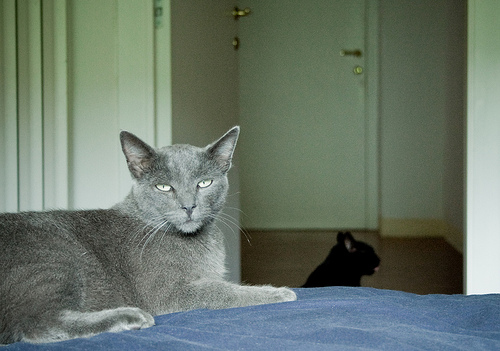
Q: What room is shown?
A: It is a bedroom.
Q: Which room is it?
A: It is a bedroom.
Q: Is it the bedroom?
A: Yes, it is the bedroom.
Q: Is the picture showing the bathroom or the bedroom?
A: It is showing the bedroom.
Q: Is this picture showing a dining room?
A: No, the picture is showing a bedroom.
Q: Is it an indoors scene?
A: Yes, it is indoors.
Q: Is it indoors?
A: Yes, it is indoors.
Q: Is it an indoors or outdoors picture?
A: It is indoors.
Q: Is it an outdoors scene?
A: No, it is indoors.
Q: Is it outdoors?
A: No, it is indoors.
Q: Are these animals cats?
A: Yes, all the animals are cats.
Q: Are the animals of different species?
A: No, all the animals are cats.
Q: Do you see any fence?
A: No, there are no fences.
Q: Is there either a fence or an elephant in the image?
A: No, there are no fences or elephants.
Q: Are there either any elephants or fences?
A: No, there are no fences or elephants.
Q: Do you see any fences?
A: No, there are no fences.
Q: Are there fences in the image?
A: No, there are no fences.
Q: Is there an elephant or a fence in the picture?
A: No, there are no fences or elephants.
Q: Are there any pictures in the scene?
A: No, there are no pictures.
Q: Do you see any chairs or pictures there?
A: No, there are no pictures or chairs.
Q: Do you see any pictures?
A: No, there are no pictures.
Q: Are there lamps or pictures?
A: No, there are no pictures or lamps.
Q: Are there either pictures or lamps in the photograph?
A: No, there are no pictures or lamps.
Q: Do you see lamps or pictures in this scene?
A: No, there are no pictures or lamps.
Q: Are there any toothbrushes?
A: No, there are no toothbrushes.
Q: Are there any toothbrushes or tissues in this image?
A: No, there are no toothbrushes or tissues.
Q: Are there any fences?
A: No, there are no fences.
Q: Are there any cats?
A: Yes, there is a cat.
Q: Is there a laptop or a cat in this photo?
A: Yes, there is a cat.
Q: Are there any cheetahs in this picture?
A: No, there are no cheetahs.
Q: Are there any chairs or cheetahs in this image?
A: No, there are no cheetahs or chairs.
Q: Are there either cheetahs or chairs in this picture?
A: No, there are no cheetahs or chairs.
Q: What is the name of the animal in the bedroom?
A: The animal is a cat.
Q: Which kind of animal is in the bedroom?
A: The animal is a cat.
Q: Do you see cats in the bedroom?
A: Yes, there is a cat in the bedroom.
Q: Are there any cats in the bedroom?
A: Yes, there is a cat in the bedroom.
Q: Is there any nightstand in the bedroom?
A: No, there is a cat in the bedroom.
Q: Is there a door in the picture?
A: Yes, there is a door.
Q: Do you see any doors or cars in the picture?
A: Yes, there is a door.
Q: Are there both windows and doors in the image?
A: No, there is a door but no windows.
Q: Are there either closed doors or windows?
A: Yes, there is a closed door.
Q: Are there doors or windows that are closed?
A: Yes, the door is closed.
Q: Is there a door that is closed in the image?
A: Yes, there is a closed door.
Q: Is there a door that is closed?
A: Yes, there is a door that is closed.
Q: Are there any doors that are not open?
A: Yes, there is an closed door.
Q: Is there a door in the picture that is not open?
A: Yes, there is an closed door.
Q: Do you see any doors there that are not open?
A: Yes, there is an closed door.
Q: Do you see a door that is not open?
A: Yes, there is an closed door.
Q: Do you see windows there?
A: No, there are no windows.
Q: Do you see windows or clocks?
A: No, there are no windows or clocks.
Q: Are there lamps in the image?
A: No, there are no lamps.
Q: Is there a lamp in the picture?
A: No, there are no lamps.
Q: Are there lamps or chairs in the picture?
A: No, there are no lamps or chairs.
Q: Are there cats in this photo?
A: Yes, there is a cat.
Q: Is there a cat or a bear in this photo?
A: Yes, there is a cat.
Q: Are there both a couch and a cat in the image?
A: No, there is a cat but no couches.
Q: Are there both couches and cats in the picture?
A: No, there is a cat but no couches.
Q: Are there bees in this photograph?
A: No, there are no bees.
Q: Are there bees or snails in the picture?
A: No, there are no bees or snails.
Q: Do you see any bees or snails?
A: No, there are no bees or snails.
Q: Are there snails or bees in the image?
A: No, there are no bees or snails.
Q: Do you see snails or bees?
A: No, there are no bees or snails.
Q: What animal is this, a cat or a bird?
A: This is a cat.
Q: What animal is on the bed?
A: The animal is a cat.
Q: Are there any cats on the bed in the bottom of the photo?
A: Yes, there is a cat on the bed.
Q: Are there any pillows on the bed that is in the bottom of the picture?
A: No, there is a cat on the bed.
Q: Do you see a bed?
A: Yes, there is a bed.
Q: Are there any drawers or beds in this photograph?
A: Yes, there is a bed.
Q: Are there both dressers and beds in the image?
A: No, there is a bed but no dressers.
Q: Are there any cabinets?
A: No, there are no cabinets.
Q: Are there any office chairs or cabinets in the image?
A: No, there are no cabinets or office chairs.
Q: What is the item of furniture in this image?
A: The piece of furniture is a bed.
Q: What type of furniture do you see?
A: The furniture is a bed.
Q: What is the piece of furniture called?
A: The piece of furniture is a bed.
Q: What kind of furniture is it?
A: The piece of furniture is a bed.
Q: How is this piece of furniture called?
A: This is a bed.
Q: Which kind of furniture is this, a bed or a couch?
A: This is a bed.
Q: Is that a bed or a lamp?
A: That is a bed.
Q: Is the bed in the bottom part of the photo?
A: Yes, the bed is in the bottom of the image.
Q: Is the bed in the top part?
A: No, the bed is in the bottom of the image.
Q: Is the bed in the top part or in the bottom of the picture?
A: The bed is in the bottom of the image.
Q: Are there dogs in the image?
A: No, there are no dogs.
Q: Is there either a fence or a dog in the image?
A: No, there are no dogs or fences.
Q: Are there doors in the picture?
A: Yes, there is a door.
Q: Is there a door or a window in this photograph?
A: Yes, there is a door.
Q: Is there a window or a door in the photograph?
A: Yes, there is a door.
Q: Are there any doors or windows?
A: Yes, there is a door.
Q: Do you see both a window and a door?
A: No, there is a door but no windows.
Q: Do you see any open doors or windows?
A: Yes, there is an open door.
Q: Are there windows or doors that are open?
A: Yes, the door is open.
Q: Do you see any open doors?
A: Yes, there is an open door.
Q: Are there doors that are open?
A: Yes, there is a door that is open.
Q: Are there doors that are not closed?
A: Yes, there is a open door.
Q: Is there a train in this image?
A: No, there are no trains.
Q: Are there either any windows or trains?
A: No, there are no trains or windows.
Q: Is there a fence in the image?
A: No, there are no fences.